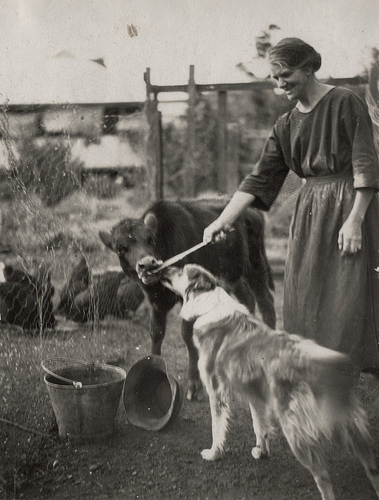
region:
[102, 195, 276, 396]
Black calf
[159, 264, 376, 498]
collie next to a calf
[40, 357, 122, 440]
metal bucket on the ground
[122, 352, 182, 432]
hat on the ground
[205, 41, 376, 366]
woman in a long dress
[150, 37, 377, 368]
woman in a dress hold a stick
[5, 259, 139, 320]
chickens in a coop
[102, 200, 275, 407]
baby cow eating off a stick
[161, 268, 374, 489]
dog licking a stick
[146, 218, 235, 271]
stick in woman's right hand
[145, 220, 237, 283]
A wooden spoon feeding the cow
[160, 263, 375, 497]
A dog in the yard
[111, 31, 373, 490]
A woman feeding the animals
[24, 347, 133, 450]
A tin bucket on the ground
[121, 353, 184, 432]
A hat on the ground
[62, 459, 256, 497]
The ground is made of dirt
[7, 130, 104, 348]
The fence is made of chicken wire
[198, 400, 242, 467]
The leg of the dog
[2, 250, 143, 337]
A group of chickens in the yard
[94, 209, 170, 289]
The head of the cow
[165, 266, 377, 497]
dog with long fur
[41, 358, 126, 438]
metal bucket on ground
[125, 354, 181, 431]
bucket hat on ground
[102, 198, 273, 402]
calf standing on ground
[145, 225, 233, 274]
wooden stick in hand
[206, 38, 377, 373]
woman wearing long dress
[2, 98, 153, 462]
chicken wire fence wrap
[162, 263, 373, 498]
dog standing by cow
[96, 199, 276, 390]
cow standing by dog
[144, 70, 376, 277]
wooden chicken coop on farm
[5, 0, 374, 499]
a woman in a farm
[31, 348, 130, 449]
an old pail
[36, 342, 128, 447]
a pail of metal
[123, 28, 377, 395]
a woman feeding animals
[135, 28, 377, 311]
woman holds a wooden spoon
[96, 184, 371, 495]
a calf and a dog licking a wooden spoon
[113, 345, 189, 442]
a straw hat on the floor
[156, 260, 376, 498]
dog has white spots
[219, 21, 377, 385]
woman wears a long skirt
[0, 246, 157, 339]
several black chikens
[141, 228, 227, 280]
the spoon the woman is holding in her hand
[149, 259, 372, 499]
the dog licking the spoon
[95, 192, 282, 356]
the little cow liking the spoon as well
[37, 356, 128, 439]
the bucket sitting on the ground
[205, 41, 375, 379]
the woman standing with the animals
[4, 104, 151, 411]
the fence next to the cow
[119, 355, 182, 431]
a hat sitting on the ground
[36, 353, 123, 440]
a bucket next to the hat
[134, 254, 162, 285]
the mouth of the cow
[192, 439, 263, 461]
the front paws of the dog